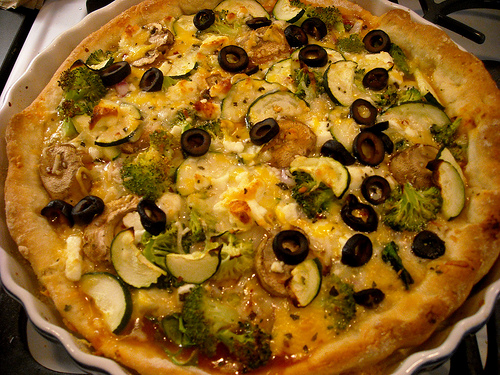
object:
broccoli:
[380, 181, 444, 233]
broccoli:
[172, 281, 245, 357]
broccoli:
[115, 130, 180, 199]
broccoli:
[52, 63, 110, 120]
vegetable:
[437, 158, 466, 222]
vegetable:
[325, 273, 355, 333]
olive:
[340, 232, 374, 266]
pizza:
[0, 0, 500, 375]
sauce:
[131, 309, 300, 375]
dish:
[0, 0, 500, 375]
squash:
[256, 231, 317, 298]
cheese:
[281, 202, 304, 223]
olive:
[248, 117, 279, 145]